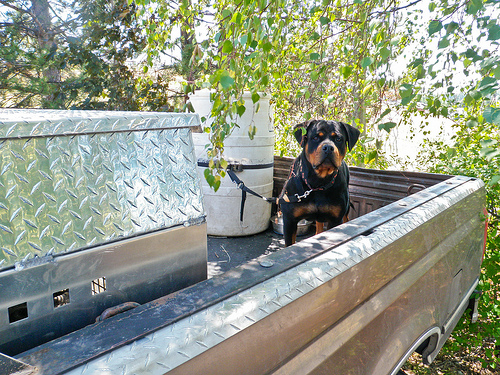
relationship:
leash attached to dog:
[197, 158, 284, 204] [258, 100, 390, 231]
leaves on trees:
[186, 16, 475, 136] [25, 7, 486, 234]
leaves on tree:
[133, 0, 376, 112] [42, 1, 481, 215]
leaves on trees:
[202, 164, 221, 193] [14, 9, 83, 87]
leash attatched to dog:
[197, 158, 284, 204] [233, 104, 369, 264]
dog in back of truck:
[258, 100, 390, 231] [52, 96, 460, 365]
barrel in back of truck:
[170, 51, 282, 249] [6, 78, 481, 373]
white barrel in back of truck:
[192, 84, 270, 236] [2, 119, 494, 369]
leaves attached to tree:
[184, 13, 277, 99] [1, 4, 277, 120]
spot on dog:
[316, 132, 325, 140] [258, 100, 390, 231]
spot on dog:
[327, 129, 338, 139] [258, 100, 390, 231]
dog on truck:
[258, 100, 390, 231] [6, 78, 481, 373]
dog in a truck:
[258, 100, 390, 231] [6, 78, 481, 373]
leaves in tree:
[223, 11, 232, 21] [125, 0, 397, 172]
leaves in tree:
[237, 104, 245, 116] [359, 0, 499, 373]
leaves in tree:
[237, 104, 245, 116] [125, 0, 397, 172]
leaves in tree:
[207, 175, 215, 187] [1, 0, 208, 115]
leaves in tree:
[212, 179, 222, 194] [359, 0, 499, 373]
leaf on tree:
[428, 15, 443, 39] [212, 2, 498, 312]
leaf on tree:
[464, 56, 474, 65] [212, 2, 498, 312]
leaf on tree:
[361, 54, 371, 66] [212, 2, 498, 312]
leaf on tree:
[481, 102, 498, 130] [212, 2, 498, 312]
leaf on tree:
[378, 120, 398, 133] [212, 2, 498, 312]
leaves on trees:
[281, 35, 451, 150] [43, 13, 493, 214]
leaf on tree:
[428, 15, 443, 39] [387, 0, 497, 177]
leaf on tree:
[378, 120, 398, 133] [387, 0, 497, 177]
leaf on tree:
[361, 147, 380, 168] [387, 0, 497, 177]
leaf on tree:
[260, 35, 275, 57] [156, 3, 228, 109]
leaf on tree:
[250, 90, 262, 105] [271, 1, 383, 123]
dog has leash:
[258, 100, 390, 231] [195, 158, 312, 220]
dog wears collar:
[258, 100, 390, 231] [278, 175, 332, 205]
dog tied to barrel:
[258, 100, 390, 231] [182, 86, 277, 238]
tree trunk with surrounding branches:
[30, 1, 64, 112] [75, 3, 418, 103]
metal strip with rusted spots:
[24, 175, 479, 369] [147, 289, 222, 311]